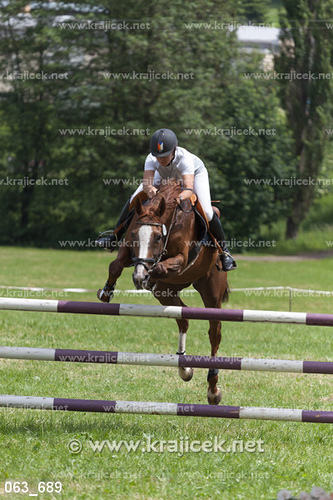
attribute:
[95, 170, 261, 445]
horse — jumping, brown, leaping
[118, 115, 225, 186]
helmet — black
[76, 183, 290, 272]
boots — black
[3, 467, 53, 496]
numbers — white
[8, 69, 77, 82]
text — white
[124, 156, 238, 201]
shirt — white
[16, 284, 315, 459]
poles — obstacles, white, stripes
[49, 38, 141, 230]
trees — green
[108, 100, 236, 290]
woman — rider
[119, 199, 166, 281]
white — black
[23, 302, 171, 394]
grass — green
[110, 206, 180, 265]
hurdle — white